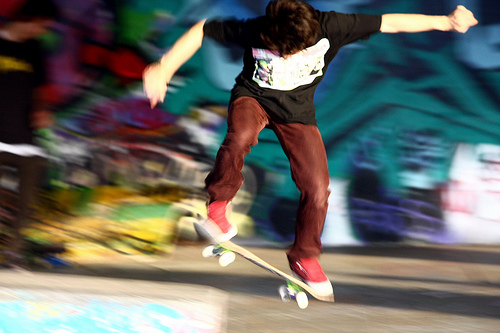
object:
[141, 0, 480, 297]
man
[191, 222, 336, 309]
skateboard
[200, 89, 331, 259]
pants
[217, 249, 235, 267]
wheels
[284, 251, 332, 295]
shoes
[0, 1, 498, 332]
background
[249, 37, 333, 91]
logo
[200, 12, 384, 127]
shirt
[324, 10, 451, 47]
arms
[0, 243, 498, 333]
ground